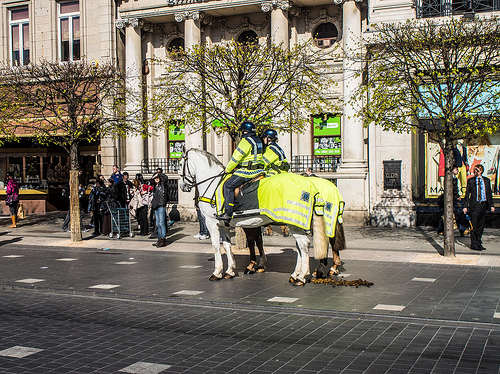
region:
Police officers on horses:
[155, 108, 370, 295]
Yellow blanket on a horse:
[212, 160, 332, 228]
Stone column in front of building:
[112, 13, 162, 165]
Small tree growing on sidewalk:
[342, 24, 476, 259]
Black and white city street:
[168, 238, 416, 355]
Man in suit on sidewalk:
[460, 151, 491, 255]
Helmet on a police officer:
[227, 117, 268, 142]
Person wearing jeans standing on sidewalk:
[145, 168, 179, 262]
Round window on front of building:
[305, 20, 342, 52]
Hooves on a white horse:
[200, 244, 242, 294]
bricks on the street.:
[95, 316, 176, 340]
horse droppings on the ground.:
[317, 273, 372, 294]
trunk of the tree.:
[64, 152, 81, 246]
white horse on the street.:
[180, 155, 215, 200]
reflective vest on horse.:
[275, 182, 309, 204]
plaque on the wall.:
[381, 156, 403, 201]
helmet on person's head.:
[265, 127, 277, 139]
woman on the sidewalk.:
[7, 174, 26, 225]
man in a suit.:
[457, 165, 492, 246]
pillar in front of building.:
[122, 23, 152, 155]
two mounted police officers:
[120, 100, 375, 300]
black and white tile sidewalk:
[11, 252, 202, 367]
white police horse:
[172, 114, 334, 292]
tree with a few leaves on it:
[17, 57, 142, 262]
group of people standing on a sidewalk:
[77, 152, 182, 251]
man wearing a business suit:
[463, 149, 491, 263]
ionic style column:
[112, 4, 156, 171]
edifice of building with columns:
[111, 3, 363, 120]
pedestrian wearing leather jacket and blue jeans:
[143, 165, 174, 254]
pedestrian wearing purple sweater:
[2, 167, 30, 232]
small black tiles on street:
[58, 311, 190, 354]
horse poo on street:
[298, 258, 429, 305]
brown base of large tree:
[52, 163, 104, 255]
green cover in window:
[299, 121, 359, 179]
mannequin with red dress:
[429, 147, 487, 192]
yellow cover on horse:
[250, 173, 322, 230]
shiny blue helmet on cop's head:
[220, 118, 265, 144]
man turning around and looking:
[465, 158, 498, 239]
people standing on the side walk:
[84, 154, 188, 238]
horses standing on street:
[154, 118, 341, 347]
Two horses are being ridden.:
[160, 124, 364, 299]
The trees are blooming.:
[365, 32, 496, 136]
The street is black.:
[70, 275, 182, 349]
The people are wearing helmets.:
[212, 116, 297, 150]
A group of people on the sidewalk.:
[79, 157, 179, 252]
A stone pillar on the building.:
[118, 9, 158, 176]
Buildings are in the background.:
[1, 1, 498, 246]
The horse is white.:
[171, 132, 352, 290]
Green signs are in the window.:
[298, 108, 352, 178]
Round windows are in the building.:
[146, 15, 371, 75]